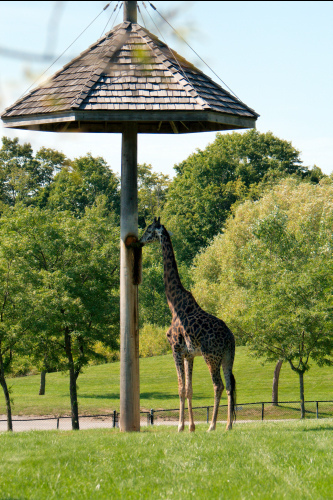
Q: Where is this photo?
A: Zoo.